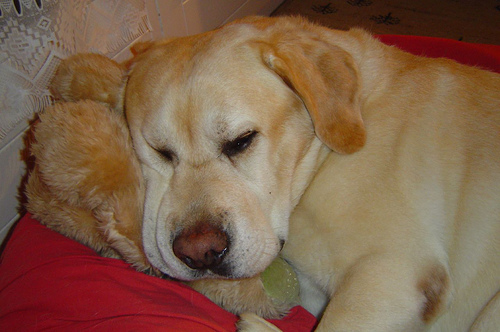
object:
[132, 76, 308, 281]
sleepy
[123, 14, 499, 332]
animal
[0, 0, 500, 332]
collor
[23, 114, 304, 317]
squished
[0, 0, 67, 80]
design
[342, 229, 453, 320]
elbow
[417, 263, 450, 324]
patch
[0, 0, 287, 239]
wall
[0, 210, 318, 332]
bed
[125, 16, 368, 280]
head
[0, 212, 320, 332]
cushion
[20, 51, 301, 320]
stuffed animal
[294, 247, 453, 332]
dog's leg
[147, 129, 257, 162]
dog's eyes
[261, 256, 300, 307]
foot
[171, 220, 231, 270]
dog's nose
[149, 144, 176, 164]
dog's eye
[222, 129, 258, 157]
dog's eye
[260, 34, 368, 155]
dog's ear